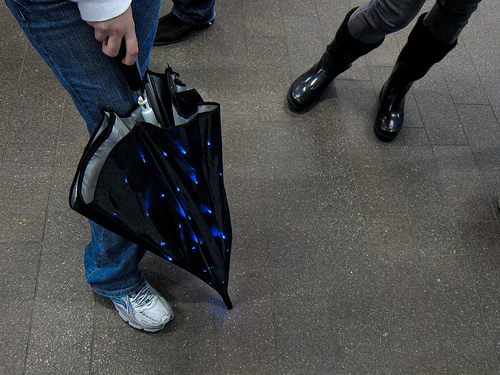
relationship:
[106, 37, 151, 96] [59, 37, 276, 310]
handle of umbrella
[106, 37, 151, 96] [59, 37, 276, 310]
handle attached to umbrella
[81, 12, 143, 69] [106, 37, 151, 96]
hand holding handle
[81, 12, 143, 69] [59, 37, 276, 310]
hand holding umbrella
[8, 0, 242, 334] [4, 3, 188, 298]
person wearing jeans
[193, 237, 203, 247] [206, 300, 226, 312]
light on floor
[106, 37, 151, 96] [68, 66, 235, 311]
handle on umbrella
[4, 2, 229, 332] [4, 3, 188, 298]
woman wearing jeans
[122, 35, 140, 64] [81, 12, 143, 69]
finger on hand